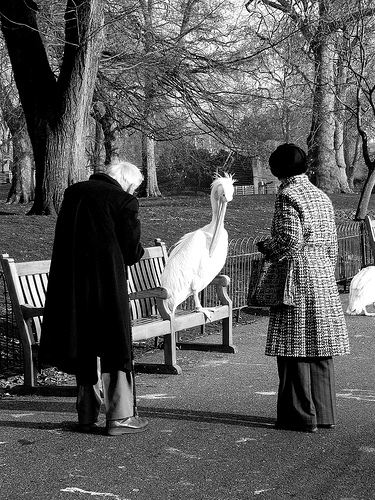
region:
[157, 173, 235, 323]
A very large white bird on a bench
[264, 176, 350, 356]
A long black and white coat on a woman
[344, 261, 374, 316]
The backend of a white bird on the ground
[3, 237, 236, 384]
Long wooden bench a bird is on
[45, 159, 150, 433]
White haired man in a long black coat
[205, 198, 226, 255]
Very long beak on a white bird who stands on a bench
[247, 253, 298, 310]
Large black and white purse a woman is holding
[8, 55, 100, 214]
A very large tree in front of a man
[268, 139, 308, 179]
A black hat on a woman's head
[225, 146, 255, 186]
Stairs behind a bird on a bench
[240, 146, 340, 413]
the woman is wearing a coat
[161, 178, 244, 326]
a bird on the bench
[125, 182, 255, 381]
a bird on the bench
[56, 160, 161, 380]
old man wearing a coat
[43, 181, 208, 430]
old man wearing a coat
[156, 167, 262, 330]
a large white bird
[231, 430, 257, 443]
a piece of white bird poop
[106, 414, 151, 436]
the shoe of a man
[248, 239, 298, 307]
a woman's handbag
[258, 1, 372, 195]
part of a tall tree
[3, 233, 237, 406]
a large wooden bench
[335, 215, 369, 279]
part of an iron gate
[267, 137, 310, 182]
a woman's black cap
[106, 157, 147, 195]
a man's white hair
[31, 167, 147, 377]
a man's long black coat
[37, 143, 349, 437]
two people observing a bird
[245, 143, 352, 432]
woman in hat holding a bag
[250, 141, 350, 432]
woman in a patterned coat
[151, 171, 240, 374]
large bird standing on a park bench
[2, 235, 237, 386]
wooden bench with three arm rests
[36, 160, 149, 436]
gentleman in a long dark coat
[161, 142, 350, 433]
woman in long coat by large bird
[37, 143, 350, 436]
two people in long outerwear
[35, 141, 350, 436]
man and woman watching a bird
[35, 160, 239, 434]
man in long jacket standing by a bird